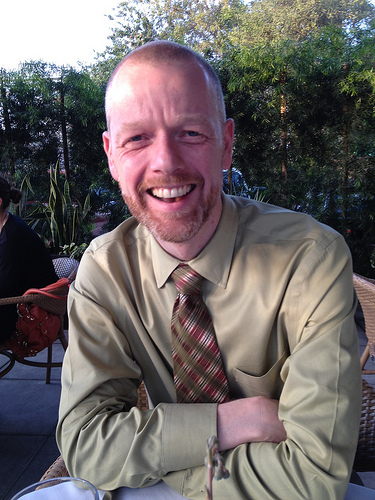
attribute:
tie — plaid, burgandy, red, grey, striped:
[169, 266, 229, 403]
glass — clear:
[8, 474, 100, 498]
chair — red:
[0, 248, 78, 386]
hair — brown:
[135, 41, 187, 76]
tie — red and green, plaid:
[173, 263, 232, 399]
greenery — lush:
[0, 0, 373, 264]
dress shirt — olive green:
[52, 189, 364, 499]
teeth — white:
[150, 183, 195, 198]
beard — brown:
[122, 192, 219, 242]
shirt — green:
[53, 220, 370, 423]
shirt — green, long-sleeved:
[64, 202, 359, 489]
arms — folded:
[49, 340, 372, 494]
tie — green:
[158, 275, 225, 398]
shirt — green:
[74, 225, 356, 475]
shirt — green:
[93, 218, 353, 493]